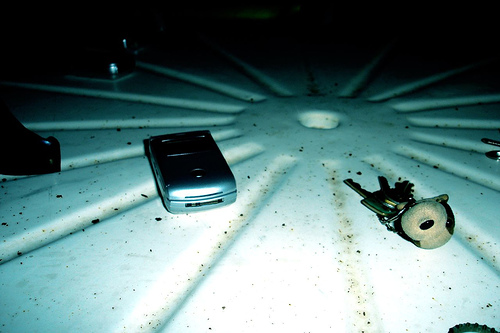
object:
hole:
[299, 110, 341, 131]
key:
[341, 176, 448, 231]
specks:
[320, 144, 377, 180]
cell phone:
[147, 129, 237, 214]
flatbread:
[235, 94, 408, 158]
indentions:
[0, 0, 500, 333]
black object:
[1, 103, 61, 175]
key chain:
[400, 202, 455, 250]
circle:
[190, 168, 205, 178]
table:
[0, 0, 500, 333]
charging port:
[185, 198, 223, 207]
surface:
[5, 65, 475, 275]